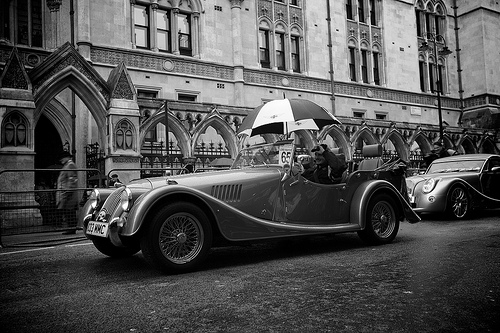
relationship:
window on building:
[133, 4, 151, 49] [0, 0, 499, 230]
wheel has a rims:
[139, 198, 214, 272] [157, 212, 204, 265]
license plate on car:
[84, 220, 111, 238] [75, 142, 421, 274]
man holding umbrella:
[303, 145, 346, 185] [235, 93, 343, 143]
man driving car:
[303, 145, 346, 185] [75, 142, 421, 274]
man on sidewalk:
[54, 150, 80, 235] [1, 229, 87, 249]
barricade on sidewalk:
[0, 168, 95, 240] [1, 229, 87, 249]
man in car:
[303, 145, 346, 185] [75, 142, 421, 274]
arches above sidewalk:
[1, 0, 500, 229] [1, 229, 87, 249]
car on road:
[75, 142, 421, 274] [0, 209, 499, 332]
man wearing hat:
[54, 150, 80, 235] [56, 151, 74, 160]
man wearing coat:
[54, 150, 80, 235] [56, 159, 78, 209]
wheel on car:
[359, 191, 400, 245] [75, 142, 421, 274]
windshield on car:
[232, 144, 295, 169] [75, 142, 421, 274]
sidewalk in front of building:
[1, 229, 87, 249] [0, 0, 499, 230]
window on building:
[258, 27, 272, 69] [0, 0, 499, 230]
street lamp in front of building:
[419, 32, 451, 139] [0, 0, 499, 230]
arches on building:
[1, 0, 500, 229] [0, 0, 499, 230]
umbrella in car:
[235, 93, 343, 143] [75, 142, 421, 274]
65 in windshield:
[281, 150, 290, 165] [232, 144, 295, 169]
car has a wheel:
[75, 142, 421, 274] [139, 198, 214, 272]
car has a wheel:
[406, 154, 499, 221] [447, 184, 471, 220]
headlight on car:
[120, 187, 133, 210] [75, 142, 421, 274]